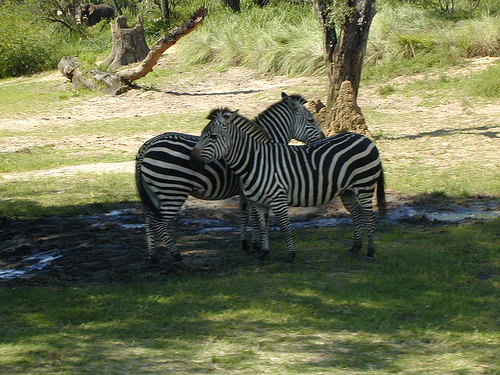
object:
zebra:
[189, 106, 388, 266]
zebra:
[134, 92, 327, 270]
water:
[0, 205, 492, 284]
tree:
[33, 0, 210, 93]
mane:
[233, 109, 273, 143]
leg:
[355, 179, 376, 252]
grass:
[0, 0, 500, 94]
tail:
[374, 153, 388, 217]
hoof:
[285, 251, 297, 263]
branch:
[59, 47, 126, 96]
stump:
[119, 5, 207, 80]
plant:
[0, 0, 57, 81]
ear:
[223, 113, 230, 120]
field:
[0, 45, 500, 375]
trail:
[103, 221, 389, 293]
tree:
[302, 0, 367, 142]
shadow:
[376, 124, 499, 151]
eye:
[208, 133, 218, 140]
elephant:
[80, 4, 115, 27]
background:
[0, 0, 500, 106]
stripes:
[260, 153, 362, 185]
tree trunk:
[304, 0, 378, 139]